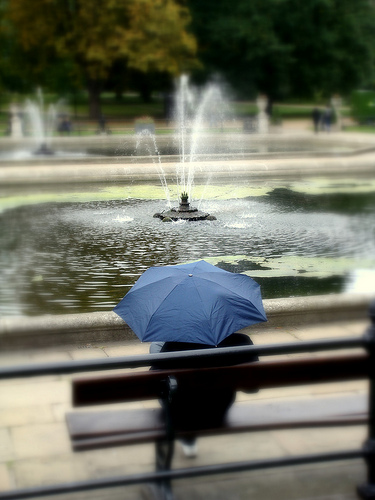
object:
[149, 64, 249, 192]
water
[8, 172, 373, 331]
ripples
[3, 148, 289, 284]
fountain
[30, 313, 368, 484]
bench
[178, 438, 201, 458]
shoe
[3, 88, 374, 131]
grass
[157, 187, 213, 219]
black fountain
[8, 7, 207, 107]
tree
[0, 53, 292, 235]
water fountain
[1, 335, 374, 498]
railing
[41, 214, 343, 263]
water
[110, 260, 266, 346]
umbrella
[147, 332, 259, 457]
man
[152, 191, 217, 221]
fountain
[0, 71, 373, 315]
water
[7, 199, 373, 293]
pond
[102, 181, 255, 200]
scum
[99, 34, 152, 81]
leaves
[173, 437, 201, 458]
shoes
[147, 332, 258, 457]
person